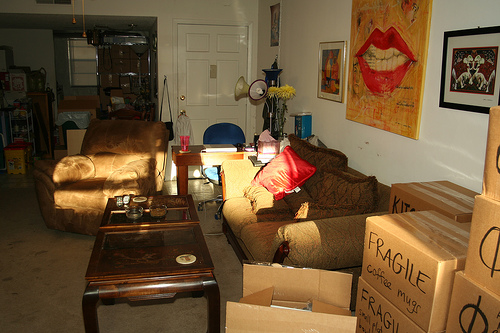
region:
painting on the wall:
[303, 10, 499, 168]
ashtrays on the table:
[101, 191, 204, 239]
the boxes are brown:
[356, 180, 481, 330]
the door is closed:
[167, 20, 259, 132]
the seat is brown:
[34, 108, 169, 227]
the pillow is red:
[239, 142, 316, 209]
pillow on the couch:
[242, 150, 313, 220]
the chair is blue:
[186, 113, 263, 186]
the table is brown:
[93, 187, 231, 308]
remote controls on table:
[106, 188, 155, 208]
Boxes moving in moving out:
[225, 199, 498, 330]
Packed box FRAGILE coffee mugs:
[355, 206, 475, 317]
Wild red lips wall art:
[343, 3, 443, 148]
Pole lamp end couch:
[232, 68, 287, 144]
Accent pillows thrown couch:
[255, 146, 379, 233]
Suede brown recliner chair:
[36, 116, 179, 229]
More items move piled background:
[2, 49, 61, 178]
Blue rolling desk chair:
[197, 111, 248, 210]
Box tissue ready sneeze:
[252, 125, 287, 162]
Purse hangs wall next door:
[159, 69, 175, 151]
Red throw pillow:
[250, 145, 315, 201]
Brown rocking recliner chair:
[25, 115, 167, 235]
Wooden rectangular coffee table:
[81, 191, 218, 329]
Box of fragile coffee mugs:
[350, 205, 486, 327]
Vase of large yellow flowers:
[258, 80, 293, 136]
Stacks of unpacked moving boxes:
[351, 102, 496, 328]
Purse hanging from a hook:
[155, 75, 175, 143]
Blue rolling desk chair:
[192, 121, 243, 214]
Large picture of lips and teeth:
[341, 0, 429, 140]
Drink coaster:
[173, 252, 197, 265]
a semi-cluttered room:
[10, 1, 495, 324]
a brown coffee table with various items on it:
[80, 186, 220, 327]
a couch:
[217, 142, 393, 273]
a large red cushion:
[247, 143, 313, 209]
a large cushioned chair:
[42, 112, 162, 232]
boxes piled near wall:
[347, 106, 497, 331]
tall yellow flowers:
[260, 77, 295, 142]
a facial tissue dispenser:
[253, 122, 283, 157]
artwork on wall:
[300, 1, 498, 156]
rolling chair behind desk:
[174, 111, 299, 208]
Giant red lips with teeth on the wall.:
[350, 26, 415, 96]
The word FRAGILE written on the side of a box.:
[366, 229, 432, 297]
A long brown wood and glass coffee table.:
[82, 196, 222, 331]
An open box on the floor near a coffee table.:
[221, 261, 356, 332]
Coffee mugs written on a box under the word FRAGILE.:
[366, 261, 421, 316]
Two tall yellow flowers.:
[265, 81, 297, 136]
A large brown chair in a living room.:
[27, 117, 172, 237]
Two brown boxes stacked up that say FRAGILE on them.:
[352, 209, 472, 331]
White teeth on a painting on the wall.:
[362, 44, 406, 71]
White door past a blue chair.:
[175, 21, 251, 146]